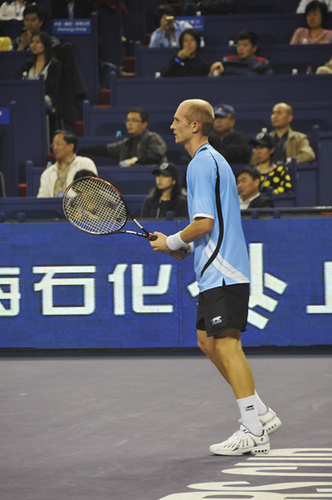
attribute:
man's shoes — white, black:
[171, 384, 280, 467]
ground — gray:
[11, 360, 198, 476]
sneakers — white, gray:
[208, 424, 271, 456]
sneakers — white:
[212, 433, 267, 458]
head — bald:
[170, 98, 215, 156]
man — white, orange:
[147, 98, 277, 453]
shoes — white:
[196, 408, 288, 460]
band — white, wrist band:
[166, 230, 186, 252]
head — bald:
[170, 98, 215, 143]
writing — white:
[108, 258, 177, 315]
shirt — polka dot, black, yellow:
[264, 161, 282, 186]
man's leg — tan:
[215, 329, 258, 396]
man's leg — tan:
[196, 326, 215, 392]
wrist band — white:
[165, 231, 195, 256]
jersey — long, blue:
[179, 142, 252, 301]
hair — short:
[176, 96, 216, 138]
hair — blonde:
[169, 91, 219, 142]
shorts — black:
[193, 281, 251, 336]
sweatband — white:
[167, 229, 191, 256]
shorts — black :
[196, 277, 248, 335]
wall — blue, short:
[1, 214, 331, 349]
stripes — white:
[205, 234, 248, 282]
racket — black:
[61, 175, 187, 257]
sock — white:
[236, 396, 262, 434]